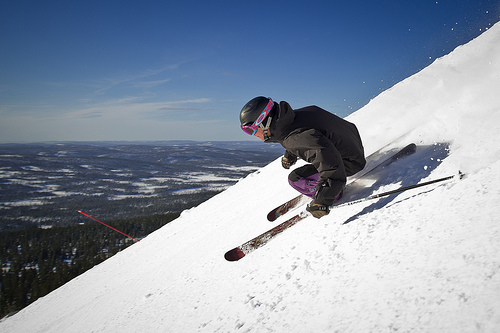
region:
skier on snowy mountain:
[216, 81, 440, 271]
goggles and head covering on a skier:
[237, 93, 279, 138]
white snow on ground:
[114, 266, 489, 316]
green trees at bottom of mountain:
[3, 223, 165, 278]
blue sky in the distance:
[7, 8, 452, 55]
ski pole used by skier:
[348, 163, 477, 202]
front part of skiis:
[210, 199, 302, 271]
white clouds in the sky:
[7, 101, 217, 141]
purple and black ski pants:
[288, 163, 318, 200]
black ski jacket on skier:
[278, 96, 367, 176]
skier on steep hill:
[110, 79, 454, 312]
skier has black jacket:
[207, 85, 407, 225]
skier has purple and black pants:
[203, 87, 372, 220]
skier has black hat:
[227, 92, 324, 179]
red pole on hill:
[24, 179, 176, 270]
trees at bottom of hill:
[36, 227, 147, 314]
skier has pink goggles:
[235, 92, 315, 153]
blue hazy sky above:
[42, 48, 244, 175]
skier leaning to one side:
[174, 79, 444, 258]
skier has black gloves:
[252, 153, 354, 258]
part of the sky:
[288, 25, 372, 73]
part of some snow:
[299, 276, 358, 317]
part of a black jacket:
[315, 146, 335, 179]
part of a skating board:
[254, 230, 275, 247]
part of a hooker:
[101, 216, 136, 238]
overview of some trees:
[45, 255, 83, 273]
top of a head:
[243, 97, 258, 116]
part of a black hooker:
[388, 178, 409, 190]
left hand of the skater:
[308, 192, 330, 227]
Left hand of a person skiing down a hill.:
[304, 197, 327, 220]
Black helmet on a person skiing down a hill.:
[237, 95, 275, 130]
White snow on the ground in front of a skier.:
[215, 209, 249, 239]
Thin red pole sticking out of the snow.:
[77, 211, 138, 243]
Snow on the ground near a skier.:
[242, 288, 284, 316]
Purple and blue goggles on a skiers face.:
[239, 96, 276, 137]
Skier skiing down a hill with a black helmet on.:
[239, 95, 366, 220]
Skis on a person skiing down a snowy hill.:
[225, 134, 416, 261]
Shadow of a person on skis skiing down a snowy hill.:
[341, 137, 451, 227]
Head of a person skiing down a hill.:
[237, 96, 279, 142]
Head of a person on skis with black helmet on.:
[240, 95, 282, 145]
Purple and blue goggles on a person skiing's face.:
[242, 95, 274, 137]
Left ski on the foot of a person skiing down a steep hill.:
[222, 140, 419, 262]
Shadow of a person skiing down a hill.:
[341, 139, 455, 224]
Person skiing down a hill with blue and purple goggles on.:
[238, 95, 365, 220]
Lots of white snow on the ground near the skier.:
[234, 285, 286, 322]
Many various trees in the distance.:
[23, 239, 52, 265]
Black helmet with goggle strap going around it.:
[238, 95, 276, 128]